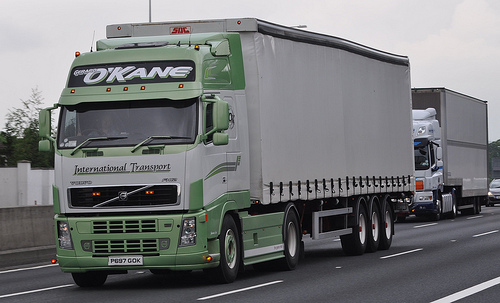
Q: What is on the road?
A: A semi truck driving down the road.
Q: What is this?
A: Windshield of semi truck.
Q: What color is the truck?
A: White and green.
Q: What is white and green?
A: A truck.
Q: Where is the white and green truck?
A: On the road.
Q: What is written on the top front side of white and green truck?
A: O'KANE.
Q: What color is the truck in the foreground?
A: White and green.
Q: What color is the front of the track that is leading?
A: White and green.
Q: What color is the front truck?
A: Green and white.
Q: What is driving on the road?
A: A truck.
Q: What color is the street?
A: Grey.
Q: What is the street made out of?
A: Concrete.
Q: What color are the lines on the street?
A: White.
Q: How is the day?
A: Overcast.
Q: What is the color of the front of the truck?
A: Green and gray.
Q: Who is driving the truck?
A: Truck driver.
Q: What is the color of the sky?
A: White and gray.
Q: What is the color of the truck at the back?
A: White.